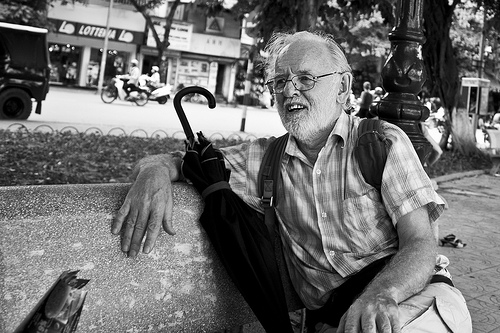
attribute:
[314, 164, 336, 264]
buttons — white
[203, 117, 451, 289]
shirt — plaid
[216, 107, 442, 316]
shirt — checkered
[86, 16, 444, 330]
man — older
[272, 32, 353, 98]
hair — balding